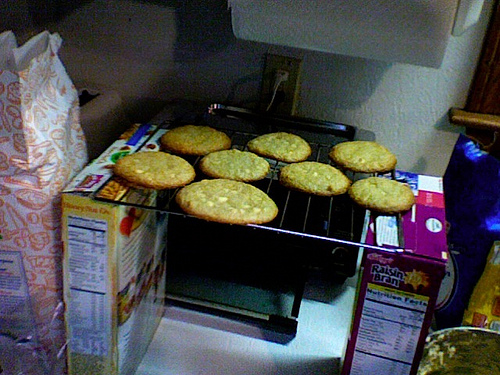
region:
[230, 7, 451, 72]
a roll of paper towels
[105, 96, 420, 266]
a wire rack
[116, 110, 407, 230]
cookies on a rack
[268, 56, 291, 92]
a plug in the wall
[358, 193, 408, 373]
a box of cereal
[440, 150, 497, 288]
a blue bag on the counter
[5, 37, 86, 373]
a white bag on the counter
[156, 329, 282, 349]
the white counter top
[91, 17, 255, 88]
the wall behind the cookies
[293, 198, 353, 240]
the wire rack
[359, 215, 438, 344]
Raisin bran cereal holding up rack.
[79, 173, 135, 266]
Tan cereal box holding up rack.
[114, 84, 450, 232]
a group of food items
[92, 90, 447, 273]
a view of food items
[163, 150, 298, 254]
a piece of food item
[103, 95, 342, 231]
a tasty food item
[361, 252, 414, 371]
a paper attached to stove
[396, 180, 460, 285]
a card in the stove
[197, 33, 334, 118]
a wire connected to socket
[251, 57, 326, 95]
a plug of the wire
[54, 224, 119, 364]
a display of chart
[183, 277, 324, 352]
a stand near the ground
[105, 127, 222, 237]
The cookies are large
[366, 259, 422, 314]
This is raisan bran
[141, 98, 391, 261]
The cookies are on a rack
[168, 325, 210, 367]
The counter is white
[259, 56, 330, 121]
Something is plugged in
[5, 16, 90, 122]
The bag is open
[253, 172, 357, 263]
The rack is metal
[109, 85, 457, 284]
8 cookies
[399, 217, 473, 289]
The box is purple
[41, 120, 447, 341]
Two boxes are lined up